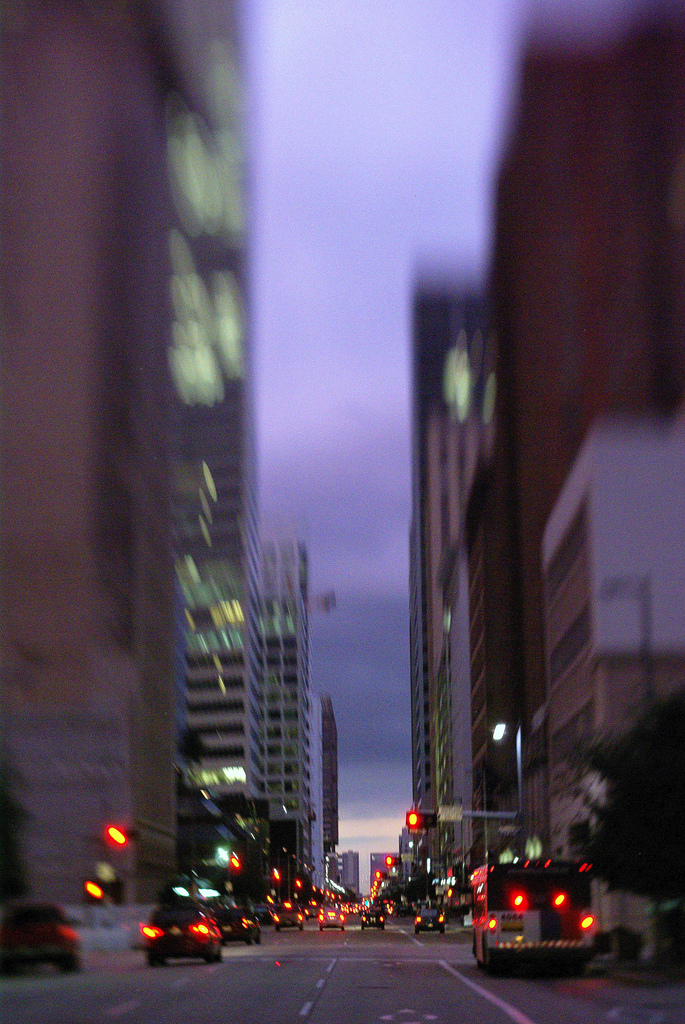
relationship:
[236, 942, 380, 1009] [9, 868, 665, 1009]
lines on road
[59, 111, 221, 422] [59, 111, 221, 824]
wall on building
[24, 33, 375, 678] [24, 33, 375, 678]
wall on building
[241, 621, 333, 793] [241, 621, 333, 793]
wall on building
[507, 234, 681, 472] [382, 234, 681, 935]
wall on building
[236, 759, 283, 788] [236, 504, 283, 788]
window on building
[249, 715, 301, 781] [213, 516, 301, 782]
window on building